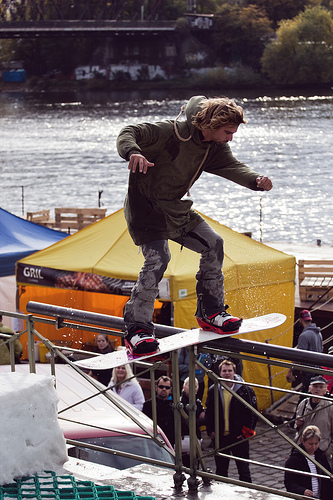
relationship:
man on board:
[115, 95, 273, 357] [70, 312, 295, 369]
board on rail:
[72, 299, 298, 359] [25, 298, 323, 364]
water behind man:
[261, 142, 304, 187] [173, 94, 245, 157]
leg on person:
[121, 219, 173, 351] [106, 75, 273, 356]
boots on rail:
[122, 318, 160, 356] [45, 295, 327, 378]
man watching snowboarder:
[115, 95, 273, 357] [112, 94, 273, 359]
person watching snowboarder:
[177, 372, 208, 473] [104, 79, 264, 330]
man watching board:
[141, 375, 175, 448] [70, 312, 287, 370]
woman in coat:
[287, 418, 332, 497] [284, 444, 331, 495]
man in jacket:
[115, 95, 273, 353] [206, 380, 254, 436]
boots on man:
[122, 318, 160, 356] [115, 95, 273, 353]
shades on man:
[157, 379, 176, 392] [149, 367, 181, 427]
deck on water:
[259, 241, 332, 310] [0, 105, 331, 244]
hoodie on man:
[116, 95, 260, 246] [115, 95, 273, 353]